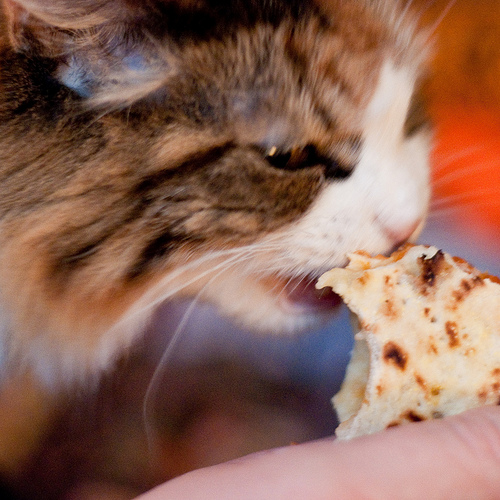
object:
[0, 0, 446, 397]
cat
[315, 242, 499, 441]
food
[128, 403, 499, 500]
hand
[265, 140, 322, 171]
eye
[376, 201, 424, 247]
nose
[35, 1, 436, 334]
head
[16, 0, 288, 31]
hair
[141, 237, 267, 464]
whisker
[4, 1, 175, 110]
ear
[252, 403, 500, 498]
finger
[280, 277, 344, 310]
lips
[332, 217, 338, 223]
hole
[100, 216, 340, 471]
whisker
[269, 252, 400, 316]
mouth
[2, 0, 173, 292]
fur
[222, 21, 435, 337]
face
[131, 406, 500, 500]
person